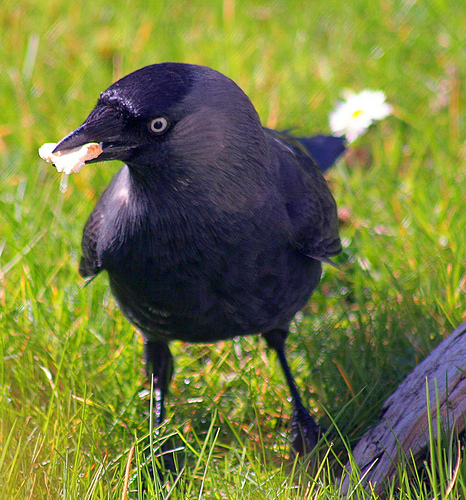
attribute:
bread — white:
[39, 140, 104, 178]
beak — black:
[50, 103, 135, 166]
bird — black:
[54, 61, 346, 479]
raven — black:
[52, 63, 349, 487]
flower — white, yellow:
[326, 86, 395, 147]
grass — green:
[1, 2, 464, 498]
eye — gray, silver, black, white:
[151, 117, 167, 134]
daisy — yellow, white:
[327, 87, 392, 142]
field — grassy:
[1, 2, 464, 499]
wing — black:
[266, 131, 343, 270]